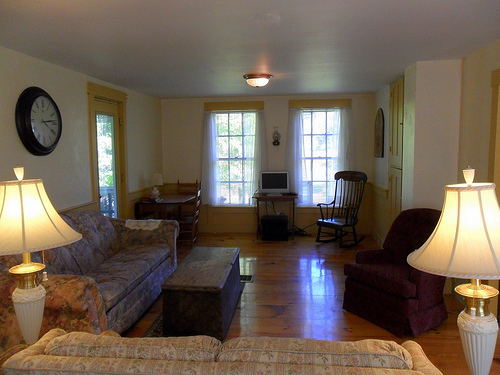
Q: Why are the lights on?
A: To see.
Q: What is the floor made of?
A: Wood.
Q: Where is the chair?
A: Next to the screen.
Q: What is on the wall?
A: Clock.